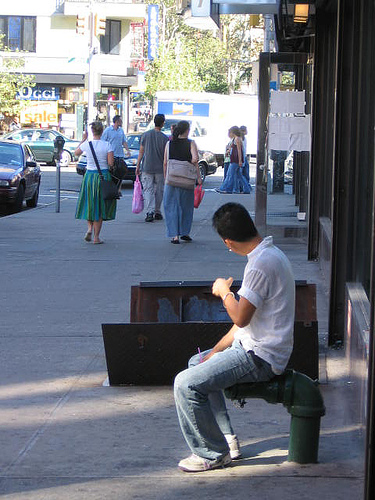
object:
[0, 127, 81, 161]
car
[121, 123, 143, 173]
car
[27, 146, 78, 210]
street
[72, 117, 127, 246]
lady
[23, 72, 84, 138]
sing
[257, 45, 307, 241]
glass door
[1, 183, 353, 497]
sidewalk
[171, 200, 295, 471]
man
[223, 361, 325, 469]
fire hydrant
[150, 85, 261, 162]
truck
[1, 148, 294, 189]
road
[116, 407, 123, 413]
stains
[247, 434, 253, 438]
stains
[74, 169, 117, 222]
green skirt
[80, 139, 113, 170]
shirt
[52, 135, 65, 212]
parking meter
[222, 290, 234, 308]
bracelet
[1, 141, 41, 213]
car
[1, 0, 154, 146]
buildings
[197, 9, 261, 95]
trees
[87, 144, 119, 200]
bag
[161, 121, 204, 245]
lady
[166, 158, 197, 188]
beige bag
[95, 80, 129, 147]
storefront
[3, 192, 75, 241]
curb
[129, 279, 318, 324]
door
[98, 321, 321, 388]
door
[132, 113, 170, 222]
pedestrians